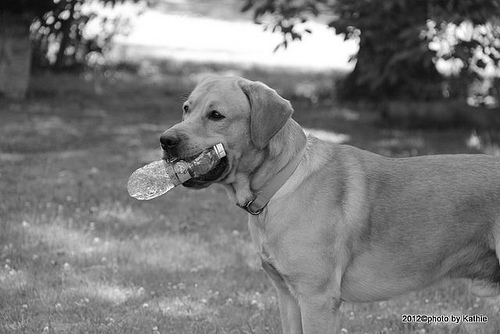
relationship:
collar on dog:
[242, 136, 311, 209] [158, 71, 498, 331]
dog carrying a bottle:
[158, 71, 498, 331] [125, 141, 225, 198]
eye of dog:
[207, 109, 227, 119] [158, 71, 498, 331]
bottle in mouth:
[126, 137, 227, 199] [158, 143, 232, 186]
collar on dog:
[238, 136, 311, 217] [158, 71, 498, 331]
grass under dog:
[1, 55, 498, 332] [158, 71, 498, 331]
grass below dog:
[1, 55, 498, 332] [158, 71, 498, 331]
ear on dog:
[238, 78, 292, 150] [158, 71, 498, 331]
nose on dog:
[156, 128, 181, 155] [158, 71, 498, 331]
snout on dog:
[159, 122, 187, 156] [158, 71, 498, 331]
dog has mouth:
[158, 71, 498, 331] [159, 142, 232, 190]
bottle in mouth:
[126, 137, 227, 199] [159, 142, 232, 190]